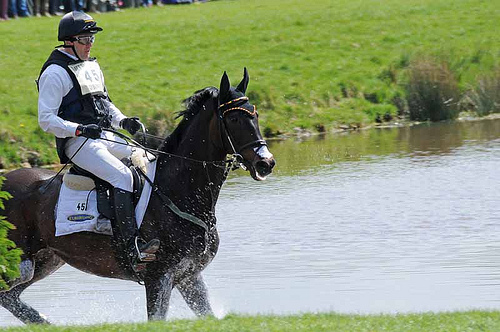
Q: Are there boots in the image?
A: Yes, there are boots.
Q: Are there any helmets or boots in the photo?
A: Yes, there are boots.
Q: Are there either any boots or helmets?
A: Yes, there are boots.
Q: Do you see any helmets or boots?
A: Yes, there are boots.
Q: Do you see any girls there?
A: No, there are no girls.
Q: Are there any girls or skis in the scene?
A: No, there are no girls or skis.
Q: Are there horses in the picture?
A: Yes, there is a horse.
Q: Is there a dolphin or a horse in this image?
A: Yes, there is a horse.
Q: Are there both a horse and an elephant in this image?
A: No, there is a horse but no elephants.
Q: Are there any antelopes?
A: No, there are no antelopes.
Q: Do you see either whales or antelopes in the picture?
A: No, there are no antelopes or whales.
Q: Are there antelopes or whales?
A: No, there are no antelopes or whales.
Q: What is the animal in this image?
A: The animal is a horse.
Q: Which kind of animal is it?
A: The animal is a horse.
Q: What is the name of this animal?
A: This is a horse.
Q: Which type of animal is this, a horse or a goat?
A: This is a horse.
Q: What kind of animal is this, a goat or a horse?
A: This is a horse.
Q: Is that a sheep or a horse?
A: That is a horse.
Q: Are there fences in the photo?
A: No, there are no fences.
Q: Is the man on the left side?
A: Yes, the man is on the left of the image.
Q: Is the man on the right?
A: No, the man is on the left of the image.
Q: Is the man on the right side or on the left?
A: The man is on the left of the image.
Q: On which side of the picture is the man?
A: The man is on the left of the image.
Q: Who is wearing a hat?
A: The man is wearing a hat.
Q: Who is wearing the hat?
A: The man is wearing a hat.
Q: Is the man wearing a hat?
A: Yes, the man is wearing a hat.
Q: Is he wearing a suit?
A: No, the man is wearing a hat.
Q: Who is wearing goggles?
A: The man is wearing goggles.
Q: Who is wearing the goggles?
A: The man is wearing goggles.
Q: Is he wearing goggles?
A: Yes, the man is wearing goggles.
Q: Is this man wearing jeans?
A: No, the man is wearing goggles.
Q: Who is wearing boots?
A: The man is wearing boots.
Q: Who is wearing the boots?
A: The man is wearing boots.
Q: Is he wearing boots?
A: Yes, the man is wearing boots.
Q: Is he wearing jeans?
A: No, the man is wearing boots.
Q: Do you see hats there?
A: Yes, there is a hat.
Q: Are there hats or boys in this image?
A: Yes, there is a hat.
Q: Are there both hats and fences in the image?
A: No, there is a hat but no fences.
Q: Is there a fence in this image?
A: No, there are no fences.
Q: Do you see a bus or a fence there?
A: No, there are no fences or buses.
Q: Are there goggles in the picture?
A: Yes, there are goggles.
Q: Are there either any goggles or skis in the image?
A: Yes, there are goggles.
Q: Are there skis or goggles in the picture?
A: Yes, there are goggles.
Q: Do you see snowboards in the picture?
A: No, there are no snowboards.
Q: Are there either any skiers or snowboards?
A: No, there are no snowboards or skiers.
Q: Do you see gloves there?
A: Yes, there are gloves.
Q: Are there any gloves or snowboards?
A: Yes, there are gloves.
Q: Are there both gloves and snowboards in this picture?
A: No, there are gloves but no snowboards.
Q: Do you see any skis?
A: No, there are no skis.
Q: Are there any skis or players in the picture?
A: No, there are no skis or players.